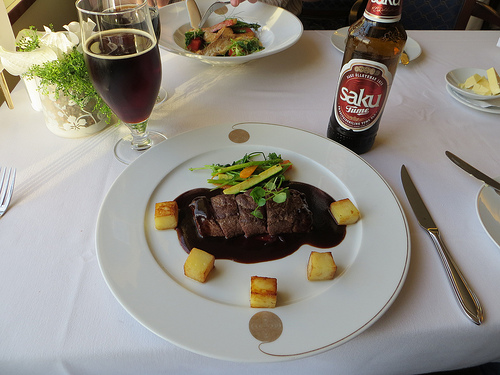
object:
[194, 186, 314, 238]
steak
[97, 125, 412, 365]
plate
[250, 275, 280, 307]
pineapple cut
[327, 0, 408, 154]
saku beer bottle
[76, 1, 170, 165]
wine glass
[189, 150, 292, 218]
garnish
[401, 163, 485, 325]
knife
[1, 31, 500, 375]
table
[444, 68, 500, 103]
plate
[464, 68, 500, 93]
butter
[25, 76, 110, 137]
vase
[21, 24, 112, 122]
plant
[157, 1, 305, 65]
bowl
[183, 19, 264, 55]
chicken salad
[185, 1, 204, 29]
piece of meat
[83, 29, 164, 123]
drink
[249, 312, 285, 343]
art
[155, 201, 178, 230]
cubed potato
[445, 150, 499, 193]
butter knife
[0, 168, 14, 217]
head of fork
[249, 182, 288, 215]
sprigs of parsely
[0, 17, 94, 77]
table decoration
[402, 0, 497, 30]
chair back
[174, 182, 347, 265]
sauce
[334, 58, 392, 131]
saku lable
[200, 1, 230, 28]
dining fork